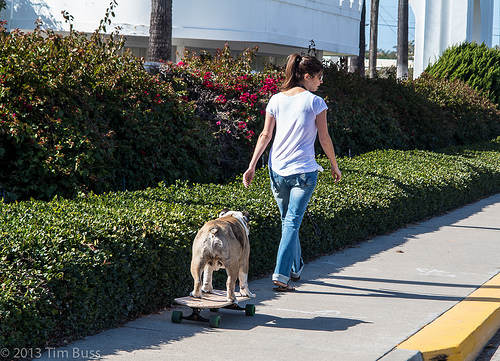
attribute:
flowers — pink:
[167, 37, 274, 150]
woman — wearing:
[238, 30, 342, 304]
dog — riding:
[195, 194, 291, 290]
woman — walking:
[238, 47, 328, 291]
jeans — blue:
[269, 167, 324, 276]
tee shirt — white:
[252, 85, 335, 179]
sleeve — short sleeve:
[309, 95, 342, 117]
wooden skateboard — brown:
[151, 209, 302, 314]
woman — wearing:
[242, 52, 339, 292]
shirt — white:
[265, 91, 327, 175]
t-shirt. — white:
[233, 76, 358, 180]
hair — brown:
[276, 42, 329, 89]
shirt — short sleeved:
[262, 90, 328, 178]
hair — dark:
[280, 50, 329, 90]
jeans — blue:
[269, 168, 314, 284]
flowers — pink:
[231, 82, 251, 103]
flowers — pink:
[247, 91, 259, 107]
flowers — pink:
[211, 93, 223, 107]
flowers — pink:
[202, 70, 212, 84]